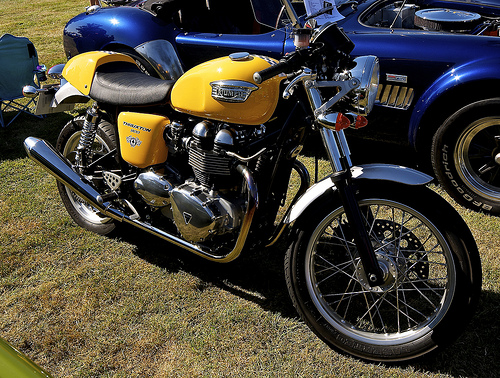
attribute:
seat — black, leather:
[97, 70, 171, 100]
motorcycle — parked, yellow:
[47, 46, 489, 358]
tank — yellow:
[173, 53, 284, 123]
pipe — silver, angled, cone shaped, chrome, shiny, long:
[18, 138, 102, 206]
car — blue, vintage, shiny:
[63, 5, 497, 52]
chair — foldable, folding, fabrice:
[3, 32, 42, 132]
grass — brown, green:
[17, 227, 91, 275]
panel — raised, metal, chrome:
[213, 82, 257, 103]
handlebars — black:
[255, 51, 324, 85]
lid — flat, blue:
[414, 11, 481, 21]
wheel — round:
[418, 19, 480, 32]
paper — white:
[310, 6, 345, 24]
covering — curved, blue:
[426, 53, 498, 80]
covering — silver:
[461, 119, 500, 132]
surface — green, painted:
[0, 337, 52, 375]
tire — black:
[280, 175, 478, 359]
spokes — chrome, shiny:
[337, 276, 393, 315]